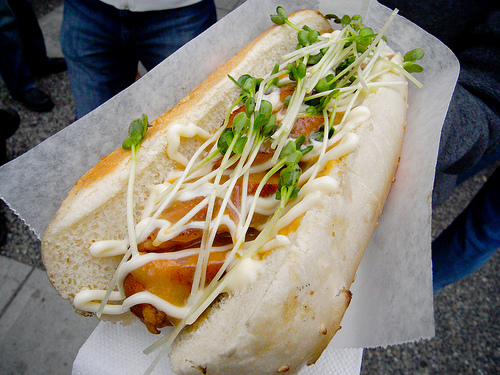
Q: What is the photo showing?
A: It is showing a walkway.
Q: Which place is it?
A: It is a walkway.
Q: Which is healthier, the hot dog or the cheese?
A: The cheese is healthier than the hot dog.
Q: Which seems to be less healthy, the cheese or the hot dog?
A: The hot dog is less healthy than the cheese.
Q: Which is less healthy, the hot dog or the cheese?
A: The hot dog is less healthy than the cheese.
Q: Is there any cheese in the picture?
A: Yes, there is cheese.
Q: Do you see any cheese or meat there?
A: Yes, there is cheese.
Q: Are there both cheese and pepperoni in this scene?
A: No, there is cheese but no pepperoni.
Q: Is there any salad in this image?
A: No, there is no salad.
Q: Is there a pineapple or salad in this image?
A: No, there are no salad or pineapples.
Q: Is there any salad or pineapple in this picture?
A: No, there are no salad or pineapples.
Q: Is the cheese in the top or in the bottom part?
A: The cheese is in the bottom of the image.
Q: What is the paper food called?
A: The food is a bun.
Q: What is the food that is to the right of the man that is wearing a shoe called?
A: The food is a bun.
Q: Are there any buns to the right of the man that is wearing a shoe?
A: Yes, there is a bun to the right of the man.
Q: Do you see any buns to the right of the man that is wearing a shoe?
A: Yes, there is a bun to the right of the man.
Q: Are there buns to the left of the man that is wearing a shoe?
A: No, the bun is to the right of the man.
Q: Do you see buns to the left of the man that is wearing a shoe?
A: No, the bun is to the right of the man.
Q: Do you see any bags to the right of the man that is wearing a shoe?
A: No, there is a bun to the right of the man.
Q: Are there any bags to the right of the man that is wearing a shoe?
A: No, there is a bun to the right of the man.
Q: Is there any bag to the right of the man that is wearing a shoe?
A: No, there is a bun to the right of the man.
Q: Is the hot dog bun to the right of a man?
A: Yes, the bun is to the right of a man.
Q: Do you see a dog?
A: Yes, there is a dog.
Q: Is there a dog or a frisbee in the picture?
A: Yes, there is a dog.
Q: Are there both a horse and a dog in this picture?
A: No, there is a dog but no horses.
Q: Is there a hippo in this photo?
A: No, there are no hippos.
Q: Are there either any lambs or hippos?
A: No, there are no hippos or lambs.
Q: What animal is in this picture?
A: The animal is a dog.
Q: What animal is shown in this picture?
A: The animal is a dog.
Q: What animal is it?
A: The animal is a dog.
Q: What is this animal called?
A: This is a dog.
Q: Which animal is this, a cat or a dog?
A: This is a dog.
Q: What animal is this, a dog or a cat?
A: This is a dog.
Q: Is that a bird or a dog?
A: That is a dog.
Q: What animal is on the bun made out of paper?
A: The dog is on the bun.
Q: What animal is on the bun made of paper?
A: The animal is a dog.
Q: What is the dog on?
A: The dog is on the bun.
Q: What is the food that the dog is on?
A: The food is a bun.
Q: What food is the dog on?
A: The dog is on the bun.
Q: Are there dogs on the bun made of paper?
A: Yes, there is a dog on the bun.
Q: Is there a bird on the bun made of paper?
A: No, there is a dog on the bun.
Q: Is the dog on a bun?
A: Yes, the dog is on a bun.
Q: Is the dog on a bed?
A: No, the dog is on a bun.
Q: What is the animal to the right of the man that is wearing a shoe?
A: The animal is a dog.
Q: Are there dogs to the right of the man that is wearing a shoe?
A: Yes, there is a dog to the right of the man.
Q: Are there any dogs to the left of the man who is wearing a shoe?
A: No, the dog is to the right of the man.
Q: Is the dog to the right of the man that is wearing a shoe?
A: Yes, the dog is to the right of the man.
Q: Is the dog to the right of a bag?
A: No, the dog is to the right of the man.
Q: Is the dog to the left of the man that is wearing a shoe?
A: No, the dog is to the right of the man.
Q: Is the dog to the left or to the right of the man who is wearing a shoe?
A: The dog is to the right of the man.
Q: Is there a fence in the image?
A: No, there are no fences.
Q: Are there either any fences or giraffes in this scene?
A: No, there are no fences or giraffes.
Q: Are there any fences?
A: No, there are no fences.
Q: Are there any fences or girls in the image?
A: No, there are no fences or girls.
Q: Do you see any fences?
A: No, there are no fences.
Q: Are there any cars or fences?
A: No, there are no fences or cars.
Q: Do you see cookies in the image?
A: No, there are no cookies.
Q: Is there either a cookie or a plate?
A: No, there are no cookies or plates.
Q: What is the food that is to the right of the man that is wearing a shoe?
A: The food is a bun.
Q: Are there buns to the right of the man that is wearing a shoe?
A: Yes, there is a bun to the right of the man.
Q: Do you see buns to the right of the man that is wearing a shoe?
A: Yes, there is a bun to the right of the man.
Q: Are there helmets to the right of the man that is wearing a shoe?
A: No, there is a bun to the right of the man.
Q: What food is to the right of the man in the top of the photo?
A: The food is a bun.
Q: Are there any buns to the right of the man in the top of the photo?
A: Yes, there is a bun to the right of the man.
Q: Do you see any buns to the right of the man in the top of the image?
A: Yes, there is a bun to the right of the man.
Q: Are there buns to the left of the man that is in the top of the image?
A: No, the bun is to the right of the man.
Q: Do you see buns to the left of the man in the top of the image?
A: No, the bun is to the right of the man.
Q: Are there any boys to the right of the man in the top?
A: No, there is a bun to the right of the man.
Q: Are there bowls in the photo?
A: No, there are no bowls.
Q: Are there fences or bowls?
A: No, there are no bowls or fences.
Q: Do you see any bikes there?
A: No, there are no bikes.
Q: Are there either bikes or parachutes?
A: No, there are no bikes or parachutes.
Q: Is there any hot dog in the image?
A: Yes, there is a hot dog.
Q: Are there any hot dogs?
A: Yes, there is a hot dog.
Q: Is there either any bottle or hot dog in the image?
A: Yes, there is a hot dog.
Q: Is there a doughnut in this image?
A: No, there are no donuts.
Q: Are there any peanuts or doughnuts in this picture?
A: No, there are no doughnuts or peanuts.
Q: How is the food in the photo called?
A: The food is a hot dog.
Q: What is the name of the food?
A: The food is a hot dog.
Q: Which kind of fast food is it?
A: The food is a hot dog.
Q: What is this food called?
A: That is a hot dog.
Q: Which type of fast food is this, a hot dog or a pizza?
A: That is a hot dog.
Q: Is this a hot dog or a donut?
A: This is a hot dog.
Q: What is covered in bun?
A: The hot dog is covered in bun.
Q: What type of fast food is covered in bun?
A: The food is a hot dog.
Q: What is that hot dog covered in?
A: The hot dog is covered in bun.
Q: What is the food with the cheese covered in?
A: The hot dog is covered in bun.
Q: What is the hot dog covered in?
A: The hot dog is covered in bun.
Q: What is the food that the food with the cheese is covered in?
A: The food is a bun.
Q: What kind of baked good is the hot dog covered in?
A: The hot dog is covered in bun.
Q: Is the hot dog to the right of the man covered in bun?
A: Yes, the hot dog is covered in bun.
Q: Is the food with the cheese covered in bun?
A: Yes, the hot dog is covered in bun.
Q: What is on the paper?
A: The hot dog is on the paper.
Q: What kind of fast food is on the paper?
A: The food is a hot dog.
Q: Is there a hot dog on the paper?
A: Yes, there is a hot dog on the paper.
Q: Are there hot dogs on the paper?
A: Yes, there is a hot dog on the paper.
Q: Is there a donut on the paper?
A: No, there is a hot dog on the paper.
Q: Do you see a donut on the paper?
A: No, there is a hot dog on the paper.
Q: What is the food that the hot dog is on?
A: The food is a bun.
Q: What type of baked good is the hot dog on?
A: The hot dog is on the bun.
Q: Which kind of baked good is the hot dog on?
A: The hot dog is on the bun.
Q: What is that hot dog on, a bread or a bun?
A: The hot dog is on a bun.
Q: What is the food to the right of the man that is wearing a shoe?
A: The food is a hot dog.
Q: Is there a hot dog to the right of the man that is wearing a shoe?
A: Yes, there is a hot dog to the right of the man.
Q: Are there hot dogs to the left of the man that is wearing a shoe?
A: No, the hot dog is to the right of the man.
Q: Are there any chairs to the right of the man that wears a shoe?
A: No, there is a hot dog to the right of the man.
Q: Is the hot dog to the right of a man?
A: Yes, the hot dog is to the right of a man.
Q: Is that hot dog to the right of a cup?
A: No, the hot dog is to the right of a man.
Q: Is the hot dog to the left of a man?
A: No, the hot dog is to the right of a man.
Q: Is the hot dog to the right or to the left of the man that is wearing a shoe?
A: The hot dog is to the right of the man.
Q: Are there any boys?
A: No, there are no boys.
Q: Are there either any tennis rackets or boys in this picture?
A: No, there are no boys or tennis rackets.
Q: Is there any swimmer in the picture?
A: No, there are no swimmers.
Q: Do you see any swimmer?
A: No, there are no swimmers.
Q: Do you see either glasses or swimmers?
A: No, there are no swimmers or glasses.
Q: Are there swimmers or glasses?
A: No, there are no swimmers or glasses.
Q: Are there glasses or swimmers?
A: No, there are no swimmers or glasses.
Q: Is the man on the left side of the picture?
A: Yes, the man is on the left of the image.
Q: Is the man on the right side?
A: No, the man is on the left of the image.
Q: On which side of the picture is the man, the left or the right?
A: The man is on the left of the image.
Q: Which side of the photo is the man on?
A: The man is on the left of the image.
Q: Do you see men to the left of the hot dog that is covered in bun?
A: Yes, there is a man to the left of the hot dog.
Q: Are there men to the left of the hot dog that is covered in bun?
A: Yes, there is a man to the left of the hot dog.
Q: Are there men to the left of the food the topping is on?
A: Yes, there is a man to the left of the hot dog.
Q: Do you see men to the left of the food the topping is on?
A: Yes, there is a man to the left of the hot dog.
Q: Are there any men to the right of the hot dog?
A: No, the man is to the left of the hot dog.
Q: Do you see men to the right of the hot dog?
A: No, the man is to the left of the hot dog.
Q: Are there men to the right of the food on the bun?
A: No, the man is to the left of the hot dog.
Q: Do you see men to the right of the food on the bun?
A: No, the man is to the left of the hot dog.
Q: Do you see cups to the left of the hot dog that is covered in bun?
A: No, there is a man to the left of the hot dog.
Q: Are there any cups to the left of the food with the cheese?
A: No, there is a man to the left of the hot dog.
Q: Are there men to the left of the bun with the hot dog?
A: Yes, there is a man to the left of the bun.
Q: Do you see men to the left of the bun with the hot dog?
A: Yes, there is a man to the left of the bun.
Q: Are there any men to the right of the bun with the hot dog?
A: No, the man is to the left of the bun.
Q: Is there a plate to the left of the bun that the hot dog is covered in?
A: No, there is a man to the left of the bun.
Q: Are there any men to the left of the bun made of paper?
A: Yes, there is a man to the left of the bun.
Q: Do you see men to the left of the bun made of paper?
A: Yes, there is a man to the left of the bun.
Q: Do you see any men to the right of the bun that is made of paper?
A: No, the man is to the left of the bun.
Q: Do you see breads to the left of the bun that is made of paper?
A: No, there is a man to the left of the bun.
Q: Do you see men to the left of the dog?
A: Yes, there is a man to the left of the dog.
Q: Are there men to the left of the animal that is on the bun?
A: Yes, there is a man to the left of the dog.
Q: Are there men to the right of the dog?
A: No, the man is to the left of the dog.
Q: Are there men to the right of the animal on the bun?
A: No, the man is to the left of the dog.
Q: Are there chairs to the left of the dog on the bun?
A: No, there is a man to the left of the dog.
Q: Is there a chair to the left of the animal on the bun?
A: No, there is a man to the left of the dog.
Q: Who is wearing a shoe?
A: The man is wearing a shoe.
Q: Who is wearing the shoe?
A: The man is wearing a shoe.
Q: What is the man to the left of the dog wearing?
A: The man is wearing a shoe.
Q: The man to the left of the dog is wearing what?
A: The man is wearing a shoe.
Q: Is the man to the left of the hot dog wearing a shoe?
A: Yes, the man is wearing a shoe.